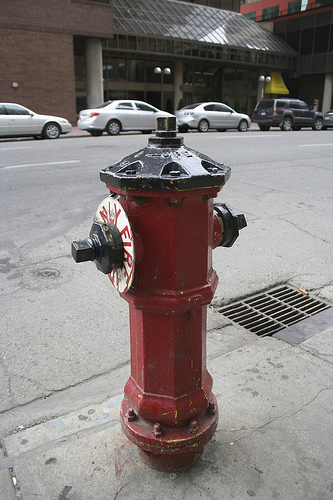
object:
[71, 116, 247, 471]
hydrant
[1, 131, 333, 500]
street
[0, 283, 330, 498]
curb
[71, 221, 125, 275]
bolts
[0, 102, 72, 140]
cars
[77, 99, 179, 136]
car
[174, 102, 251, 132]
car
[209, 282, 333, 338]
drain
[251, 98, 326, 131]
suv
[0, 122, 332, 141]
pedestrian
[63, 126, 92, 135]
walkway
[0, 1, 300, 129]
building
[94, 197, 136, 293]
sign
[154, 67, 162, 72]
lamp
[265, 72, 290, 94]
canopy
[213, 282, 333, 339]
cover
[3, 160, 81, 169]
markings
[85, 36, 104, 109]
pillar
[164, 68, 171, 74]
lights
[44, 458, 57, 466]
mark